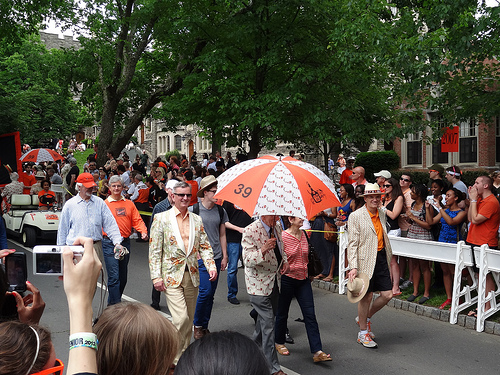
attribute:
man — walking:
[241, 215, 290, 373]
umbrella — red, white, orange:
[212, 155, 344, 239]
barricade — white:
[339, 225, 499, 333]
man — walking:
[56, 171, 130, 264]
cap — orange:
[75, 171, 98, 188]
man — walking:
[348, 182, 395, 349]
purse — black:
[302, 228, 324, 277]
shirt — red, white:
[280, 228, 313, 281]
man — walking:
[149, 181, 221, 366]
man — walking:
[103, 174, 149, 306]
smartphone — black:
[5, 250, 28, 294]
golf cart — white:
[2, 193, 63, 247]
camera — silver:
[33, 245, 88, 278]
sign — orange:
[441, 125, 461, 165]